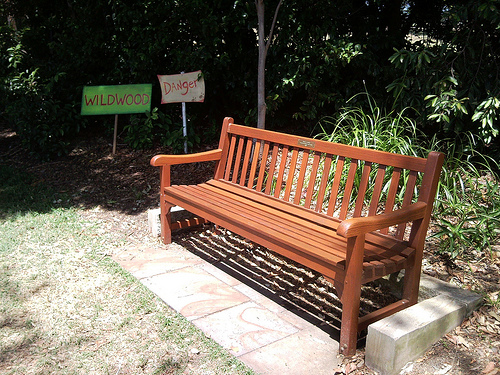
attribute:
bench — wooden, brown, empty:
[149, 115, 443, 357]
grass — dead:
[0, 204, 252, 374]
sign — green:
[78, 83, 153, 117]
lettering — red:
[85, 93, 150, 107]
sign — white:
[154, 69, 207, 103]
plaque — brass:
[295, 138, 318, 149]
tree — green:
[1, 2, 121, 149]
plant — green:
[310, 82, 491, 209]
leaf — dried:
[336, 364, 367, 372]